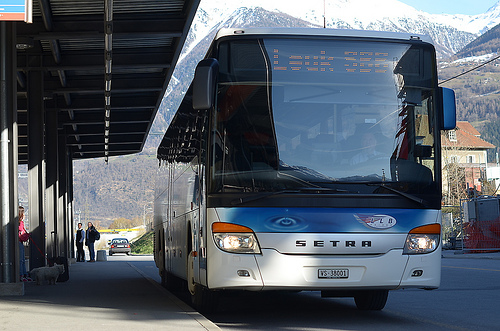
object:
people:
[76, 222, 86, 261]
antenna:
[322, 0, 327, 29]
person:
[13, 200, 33, 282]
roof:
[0, 2, 200, 159]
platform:
[0, 260, 219, 330]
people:
[85, 222, 100, 263]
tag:
[318, 268, 350, 279]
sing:
[272, 48, 388, 75]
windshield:
[215, 36, 434, 183]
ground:
[428, 83, 433, 87]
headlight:
[212, 232, 262, 254]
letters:
[274, 48, 390, 73]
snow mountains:
[242, 0, 291, 23]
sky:
[60, 3, 182, 150]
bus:
[152, 27, 456, 312]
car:
[106, 237, 131, 255]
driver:
[348, 129, 390, 166]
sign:
[272, 48, 388, 73]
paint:
[440, 261, 498, 275]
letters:
[321, 270, 327, 276]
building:
[1, 0, 200, 298]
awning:
[0, 2, 202, 161]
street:
[94, 225, 162, 282]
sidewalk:
[0, 257, 227, 331]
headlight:
[401, 233, 441, 255]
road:
[115, 249, 498, 330]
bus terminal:
[0, 0, 197, 299]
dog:
[29, 262, 65, 285]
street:
[108, 247, 498, 330]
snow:
[334, 0, 376, 30]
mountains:
[321, 1, 417, 31]